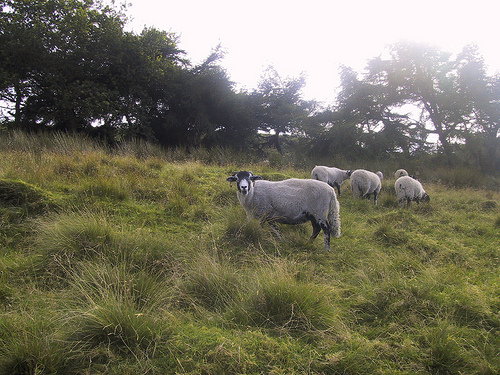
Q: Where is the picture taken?
A: Oudoor.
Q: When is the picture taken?
A: Daytime.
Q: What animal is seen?
A: Sheep.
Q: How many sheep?
A: 6.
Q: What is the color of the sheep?
A: Grey.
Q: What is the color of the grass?
A: Green.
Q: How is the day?
A: Sunny.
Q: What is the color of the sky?
A: White.